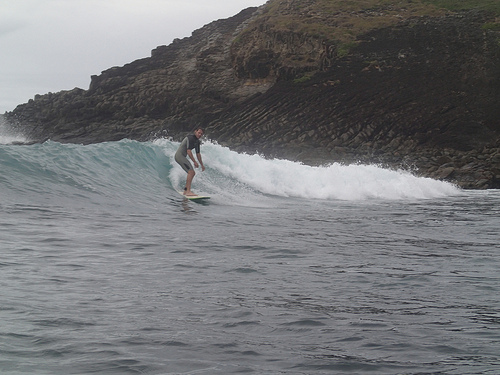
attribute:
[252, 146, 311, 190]
wave — white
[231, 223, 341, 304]
water — grey, blue, green, rough, choppy, buoyant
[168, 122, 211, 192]
man — grey, barefoot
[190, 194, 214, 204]
surfboard — white, grey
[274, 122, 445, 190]
shore — rocky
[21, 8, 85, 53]
sky — grey, overcast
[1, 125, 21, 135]
water — splashing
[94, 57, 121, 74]
ridge — rocky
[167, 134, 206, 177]
wet suit — grey, black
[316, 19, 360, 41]
grass — sparse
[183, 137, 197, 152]
sleeves — short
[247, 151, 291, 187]
foam — white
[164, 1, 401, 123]
mountain — rocky